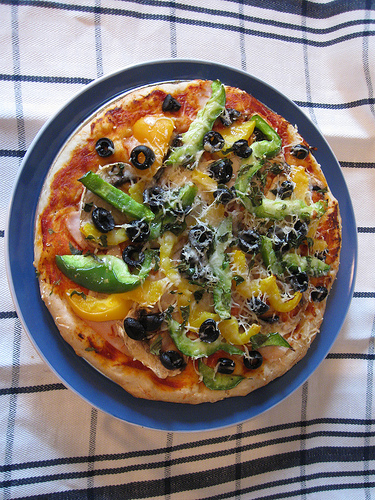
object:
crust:
[111, 363, 149, 400]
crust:
[40, 293, 74, 326]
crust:
[263, 347, 292, 375]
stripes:
[0, 0, 375, 499]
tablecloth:
[1, 2, 374, 499]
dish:
[4, 57, 357, 434]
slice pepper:
[55, 79, 330, 391]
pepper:
[77, 170, 156, 222]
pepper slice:
[233, 114, 282, 196]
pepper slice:
[259, 235, 284, 277]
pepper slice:
[167, 318, 245, 359]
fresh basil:
[69, 241, 84, 255]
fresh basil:
[70, 290, 86, 300]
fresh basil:
[49, 279, 61, 296]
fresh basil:
[48, 228, 55, 234]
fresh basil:
[84, 234, 96, 241]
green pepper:
[55, 250, 152, 295]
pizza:
[33, 78, 343, 405]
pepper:
[123, 113, 177, 181]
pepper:
[231, 249, 303, 312]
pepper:
[55, 250, 153, 294]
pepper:
[166, 78, 226, 165]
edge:
[104, 403, 155, 432]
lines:
[223, 0, 375, 19]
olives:
[203, 131, 225, 154]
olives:
[140, 309, 164, 332]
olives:
[124, 317, 147, 341]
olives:
[159, 350, 183, 371]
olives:
[199, 319, 221, 343]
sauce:
[37, 78, 341, 391]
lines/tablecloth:
[0, 0, 375, 48]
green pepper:
[77, 170, 156, 221]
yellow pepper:
[230, 250, 302, 312]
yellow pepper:
[176, 276, 262, 346]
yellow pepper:
[160, 229, 195, 292]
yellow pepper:
[66, 277, 170, 323]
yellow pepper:
[124, 113, 174, 181]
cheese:
[79, 96, 332, 384]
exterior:
[4, 58, 357, 433]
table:
[1, 1, 374, 500]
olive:
[209, 159, 234, 185]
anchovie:
[130, 145, 155, 170]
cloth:
[0, 0, 375, 499]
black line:
[0, 413, 375, 499]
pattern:
[0, 0, 375, 500]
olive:
[217, 357, 236, 375]